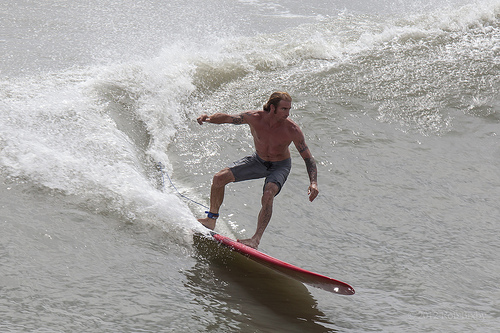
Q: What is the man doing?
A: Surfing.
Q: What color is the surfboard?
A: Red.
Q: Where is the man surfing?
A: In the ocean.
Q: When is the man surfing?
A: During the day.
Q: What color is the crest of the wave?
A: White.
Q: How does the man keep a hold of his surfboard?
A: With a rope.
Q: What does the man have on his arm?
A: Tattoos.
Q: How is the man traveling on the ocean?
A: By surfing.